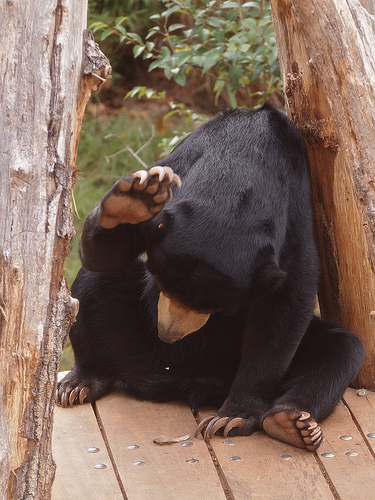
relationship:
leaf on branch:
[166, 107, 180, 120] [127, 85, 207, 129]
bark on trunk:
[284, 77, 309, 116] [273, 2, 374, 391]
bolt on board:
[135, 457, 144, 465] [97, 379, 227, 499]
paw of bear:
[97, 164, 182, 249] [56, 107, 363, 452]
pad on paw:
[102, 192, 152, 232] [97, 164, 182, 249]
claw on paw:
[133, 170, 150, 185] [97, 164, 182, 249]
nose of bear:
[155, 286, 215, 349] [56, 107, 363, 452]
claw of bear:
[133, 170, 150, 185] [56, 107, 363, 452]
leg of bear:
[260, 305, 364, 420] [56, 107, 363, 452]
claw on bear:
[133, 170, 150, 185] [56, 107, 363, 452]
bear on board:
[56, 107, 363, 452] [97, 379, 227, 499]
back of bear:
[152, 105, 291, 140] [56, 107, 363, 452]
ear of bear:
[256, 264, 284, 294] [56, 107, 363, 452]